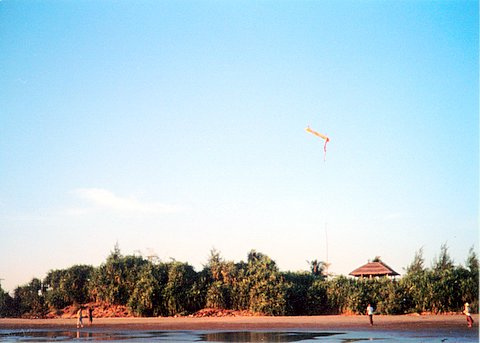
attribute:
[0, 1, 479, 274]
sky — light blue, clear, cloudy, blue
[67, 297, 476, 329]
people — watching, walking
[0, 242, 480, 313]
trees — green, grouped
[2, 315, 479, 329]
beach — sandy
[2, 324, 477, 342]
water — dark, reflecting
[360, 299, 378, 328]
person — walking, female, standing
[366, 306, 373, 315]
shirt — white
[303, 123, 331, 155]
kite — flying, yellow, high, red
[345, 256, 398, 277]
roof — brown